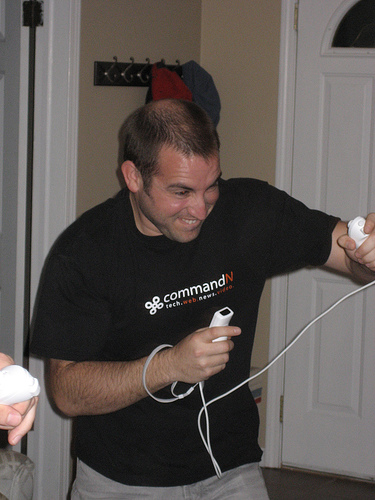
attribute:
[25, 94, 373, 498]
man — playing